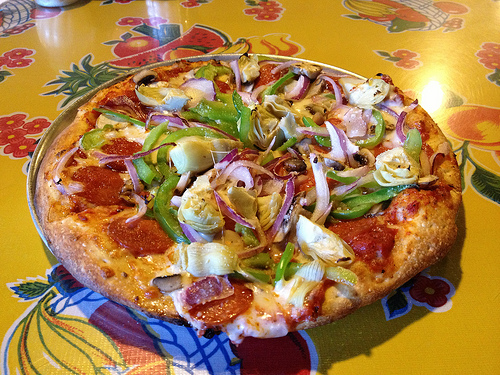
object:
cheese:
[33, 54, 461, 344]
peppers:
[35, 54, 461, 347]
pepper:
[92, 108, 146, 127]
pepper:
[325, 170, 361, 185]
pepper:
[273, 242, 295, 288]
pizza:
[33, 52, 461, 347]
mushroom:
[345, 74, 395, 110]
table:
[311, 0, 347, 19]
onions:
[267, 179, 295, 249]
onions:
[213, 190, 256, 230]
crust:
[358, 218, 436, 284]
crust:
[412, 189, 456, 231]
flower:
[245, 0, 283, 22]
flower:
[0, 48, 33, 68]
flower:
[0, 113, 51, 158]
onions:
[309, 153, 333, 225]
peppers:
[185, 126, 205, 135]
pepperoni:
[98, 136, 142, 170]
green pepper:
[141, 121, 169, 152]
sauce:
[348, 221, 392, 244]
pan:
[18, 51, 370, 260]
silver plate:
[34, 141, 46, 153]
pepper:
[284, 262, 303, 277]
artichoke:
[152, 173, 191, 245]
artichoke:
[331, 183, 418, 219]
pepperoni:
[70, 166, 125, 207]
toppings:
[55, 57, 422, 286]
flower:
[409, 276, 451, 308]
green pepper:
[92, 108, 145, 127]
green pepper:
[261, 72, 293, 103]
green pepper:
[153, 176, 190, 244]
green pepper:
[232, 89, 252, 148]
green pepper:
[132, 157, 156, 184]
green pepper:
[79, 124, 113, 151]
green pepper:
[355, 109, 386, 148]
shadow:
[334, 330, 365, 351]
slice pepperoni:
[180, 276, 223, 306]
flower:
[392, 49, 419, 69]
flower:
[7, 265, 85, 302]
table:
[468, 123, 499, 157]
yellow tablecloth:
[0, 0, 498, 374]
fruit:
[0, 288, 128, 375]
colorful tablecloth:
[368, 2, 500, 54]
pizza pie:
[34, 59, 457, 344]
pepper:
[330, 183, 416, 219]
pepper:
[132, 151, 156, 184]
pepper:
[261, 68, 295, 103]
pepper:
[195, 62, 235, 80]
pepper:
[354, 108, 386, 147]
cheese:
[172, 285, 256, 339]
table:
[0, 0, 72, 29]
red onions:
[322, 120, 348, 160]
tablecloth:
[0, 0, 500, 375]